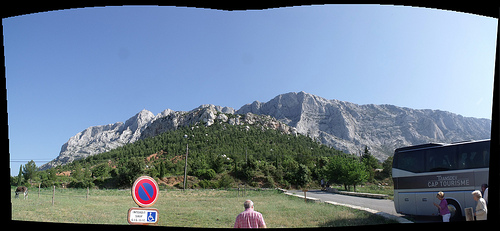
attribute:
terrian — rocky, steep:
[12, 92, 490, 190]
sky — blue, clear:
[0, 7, 498, 174]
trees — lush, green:
[11, 120, 374, 188]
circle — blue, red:
[128, 170, 165, 210]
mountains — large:
[36, 90, 492, 170]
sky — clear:
[90, 42, 131, 94]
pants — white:
[442, 210, 452, 222]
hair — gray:
[239, 196, 257, 211]